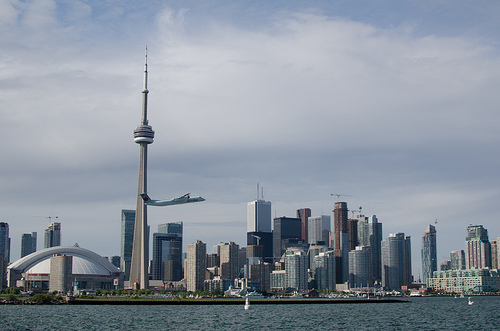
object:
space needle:
[128, 44, 154, 290]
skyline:
[0, 183, 499, 252]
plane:
[136, 191, 206, 206]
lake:
[0, 308, 89, 331]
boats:
[238, 286, 265, 301]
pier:
[76, 299, 411, 305]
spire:
[254, 182, 259, 200]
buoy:
[242, 297, 249, 311]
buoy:
[466, 295, 473, 306]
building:
[331, 202, 350, 282]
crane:
[330, 192, 356, 202]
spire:
[260, 185, 265, 201]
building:
[247, 200, 271, 233]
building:
[161, 240, 183, 281]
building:
[6, 246, 121, 296]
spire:
[141, 43, 150, 126]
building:
[348, 245, 373, 289]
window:
[75, 280, 87, 289]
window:
[100, 281, 113, 289]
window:
[40, 280, 48, 294]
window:
[33, 280, 41, 295]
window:
[27, 279, 31, 293]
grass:
[73, 292, 95, 304]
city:
[7, 153, 490, 286]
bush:
[6, 294, 21, 305]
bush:
[31, 293, 55, 303]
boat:
[459, 293, 464, 299]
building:
[121, 209, 136, 280]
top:
[121, 209, 135, 220]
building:
[428, 270, 500, 295]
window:
[438, 279, 441, 283]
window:
[453, 277, 458, 282]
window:
[431, 284, 434, 288]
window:
[475, 277, 480, 280]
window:
[445, 283, 449, 288]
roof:
[8, 245, 123, 275]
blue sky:
[90, 0, 500, 31]